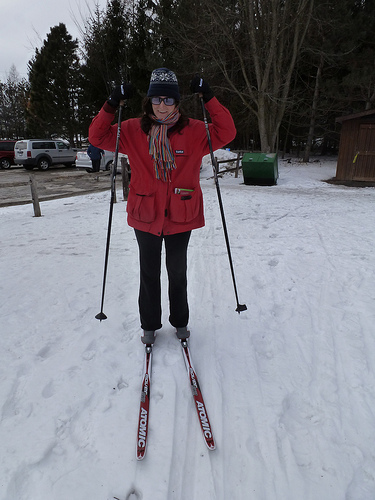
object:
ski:
[179, 337, 216, 451]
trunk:
[303, 36, 325, 162]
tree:
[153, 0, 362, 160]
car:
[13, 139, 78, 170]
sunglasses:
[151, 96, 176, 106]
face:
[152, 96, 175, 121]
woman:
[88, 67, 235, 346]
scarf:
[147, 102, 181, 181]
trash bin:
[241, 151, 278, 186]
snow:
[0, 148, 375, 500]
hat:
[148, 66, 180, 101]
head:
[148, 68, 179, 123]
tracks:
[163, 350, 190, 500]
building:
[333, 105, 375, 183]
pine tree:
[21, 20, 85, 152]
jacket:
[87, 98, 236, 237]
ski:
[98, 100, 124, 323]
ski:
[198, 92, 241, 314]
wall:
[336, 115, 375, 182]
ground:
[0, 134, 375, 500]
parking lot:
[0, 156, 127, 207]